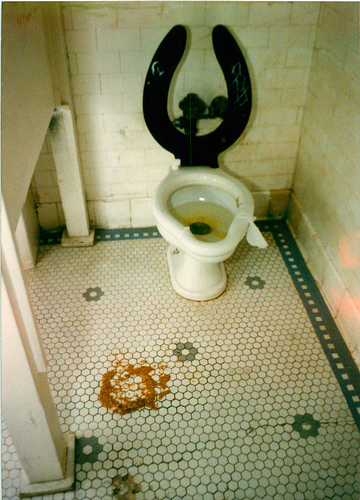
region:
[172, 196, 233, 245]
dirty toilet water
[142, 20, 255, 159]
lid to toilet seat left up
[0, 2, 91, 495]
white wood privacy wall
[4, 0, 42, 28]
red writing on wall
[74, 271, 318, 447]
tile laid in flower pattern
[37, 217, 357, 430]
tile border around wall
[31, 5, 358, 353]
white wall tile that is dirty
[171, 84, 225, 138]
pump that helps flush contents of toilet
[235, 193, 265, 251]
toilet paper stuck to toilet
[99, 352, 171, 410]
pile of mud on floor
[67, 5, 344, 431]
a public bathroom toilet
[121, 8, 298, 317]
a dirty bathroom toilet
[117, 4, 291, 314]
a dirty white toilet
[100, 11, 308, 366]
a white toilet with black seat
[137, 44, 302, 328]
a toilet with graffiti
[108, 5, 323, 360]
a dirty toilet with graffiti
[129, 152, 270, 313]
a toilet with toilet paper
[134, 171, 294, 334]
toilet paper on a toilet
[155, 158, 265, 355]
toilet paper on white toilet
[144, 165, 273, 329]
toilet paper on bathroom toilet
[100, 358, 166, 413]
Vomit on the ground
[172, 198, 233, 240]
Water in the toilet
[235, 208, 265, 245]
Toilet paper on the toilet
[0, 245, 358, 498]
The ground beneath the toilet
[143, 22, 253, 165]
The black seat of the toilet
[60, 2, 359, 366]
The dirty wall near the toilet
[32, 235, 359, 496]
The floor has a hexagon pattern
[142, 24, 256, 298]
A toilet in a dirty room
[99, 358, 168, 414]
Vomit near the dirty toilet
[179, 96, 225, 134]
Pipes behind the toilet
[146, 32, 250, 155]
black toilet seat is up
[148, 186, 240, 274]
white toilet seat rim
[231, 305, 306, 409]
white and green tile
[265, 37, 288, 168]
white and tile wall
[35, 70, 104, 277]
white toilet stall dividers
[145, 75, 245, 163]
black toilet flush handle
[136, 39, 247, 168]
black and round toilet seat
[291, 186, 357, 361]
white base of wall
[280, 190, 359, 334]
base of wall is tiled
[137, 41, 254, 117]
white writing on toilet seat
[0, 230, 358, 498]
White floor tiles shaped liked hexagons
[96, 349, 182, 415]
Orange pile of vomit that has been stepped in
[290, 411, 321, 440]
Green tile pattern resembling a flower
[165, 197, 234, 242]
Urine and stains in a filthy toilet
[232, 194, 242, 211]
Poop that someone left on the rim of a toilet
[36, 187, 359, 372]
Dirty white baseboard tiles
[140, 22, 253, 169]
Black industrial toilet seat in the up position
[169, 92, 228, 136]
Plumbing and flush valve of an industrial toilet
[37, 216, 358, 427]
Green floor tiles with small white tile squares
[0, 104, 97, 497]
Dirty legs of a restroom partition